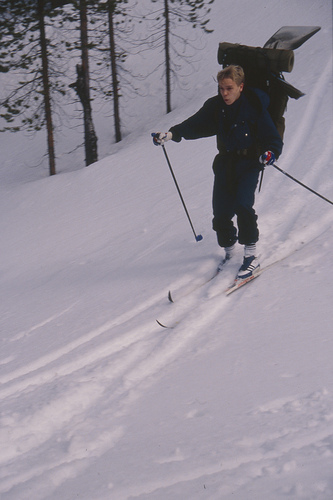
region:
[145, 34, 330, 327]
skier coming down the mountain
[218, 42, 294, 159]
backpack skier is wearing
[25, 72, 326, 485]
tracks in the snowfall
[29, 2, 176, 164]
four trees along the mountainside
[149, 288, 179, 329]
tips of the skis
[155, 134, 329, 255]
black ski poles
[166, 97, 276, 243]
dark blue skisuit skier is wearing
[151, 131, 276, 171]
white and red gloves skier is wearing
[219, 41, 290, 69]
bed roll on backpack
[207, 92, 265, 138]
straps of the backpack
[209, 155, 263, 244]
boy wearing blue pants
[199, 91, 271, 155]
boy wearing a blue jacket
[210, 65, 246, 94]
boy with blonde hair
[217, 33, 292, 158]
boy wearing a backpack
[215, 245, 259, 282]
boy wearing snow boots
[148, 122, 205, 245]
man holding a ski pole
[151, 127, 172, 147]
man wearing snow gloves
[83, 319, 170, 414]
ski trails in the snow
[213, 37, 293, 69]
sleeping bag on the backpack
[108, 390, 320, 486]
snow on the ground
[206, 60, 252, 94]
boy has blond hair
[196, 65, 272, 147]
blue and black coat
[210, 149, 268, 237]
boy has black pants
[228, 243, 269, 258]
boy has white socks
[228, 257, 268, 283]
blue and white shoes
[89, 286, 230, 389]
tracks in white snow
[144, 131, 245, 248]
boy holds black poles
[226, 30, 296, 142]
brown bag on back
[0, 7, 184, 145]
thin branches on trees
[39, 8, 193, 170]
few trees behind boy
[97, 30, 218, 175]
white snow on the ground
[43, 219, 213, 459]
white snow on the ground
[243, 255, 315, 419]
white snow on the ground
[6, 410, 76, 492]
white snow on the ground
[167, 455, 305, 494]
white snow on the ground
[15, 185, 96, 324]
white snow on the ground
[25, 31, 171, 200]
white snow on the ground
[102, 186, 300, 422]
white snow on the ground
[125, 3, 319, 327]
white snow on the ground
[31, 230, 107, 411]
white snow on the ground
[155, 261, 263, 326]
a couple of skiboards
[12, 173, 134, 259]
the snow covering the mountains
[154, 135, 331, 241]
two ski poles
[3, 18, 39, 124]
some tree branches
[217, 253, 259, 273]
a couple of blue ski boots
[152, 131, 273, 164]
a couple of blue and white gloves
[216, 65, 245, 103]
the head of the skier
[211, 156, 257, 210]
a dark blue pant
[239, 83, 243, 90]
one ear of the skier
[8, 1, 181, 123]
four trees in the background